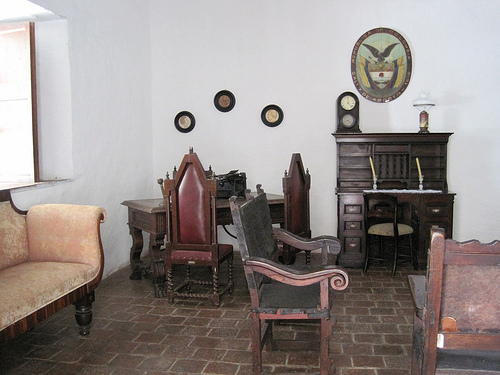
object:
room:
[0, 0, 500, 375]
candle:
[369, 156, 378, 190]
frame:
[174, 111, 195, 134]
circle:
[214, 90, 235, 114]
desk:
[331, 131, 456, 269]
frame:
[350, 26, 413, 104]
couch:
[0, 188, 107, 364]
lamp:
[412, 92, 435, 134]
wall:
[86, 0, 500, 143]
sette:
[206, 183, 362, 375]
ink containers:
[416, 157, 425, 190]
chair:
[163, 147, 233, 310]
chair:
[228, 184, 350, 374]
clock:
[334, 91, 362, 133]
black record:
[261, 104, 284, 128]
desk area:
[120, 191, 285, 298]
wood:
[73, 289, 84, 299]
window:
[0, 0, 73, 196]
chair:
[363, 192, 419, 277]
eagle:
[362, 42, 400, 62]